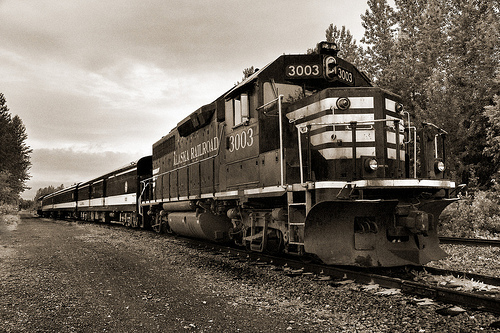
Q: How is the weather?
A: It is cloudy.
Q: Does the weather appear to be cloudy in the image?
A: Yes, it is cloudy.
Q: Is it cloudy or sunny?
A: It is cloudy.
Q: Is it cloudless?
A: No, it is cloudy.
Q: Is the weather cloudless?
A: No, it is cloudy.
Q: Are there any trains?
A: Yes, there is a train.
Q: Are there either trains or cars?
A: Yes, there is a train.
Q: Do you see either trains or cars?
A: Yes, there is a train.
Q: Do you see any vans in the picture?
A: No, there are no vans.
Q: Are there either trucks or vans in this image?
A: No, there are no vans or trucks.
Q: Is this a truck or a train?
A: This is a train.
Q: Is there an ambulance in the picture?
A: No, there are no ambulances.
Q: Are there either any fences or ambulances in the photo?
A: No, there are no ambulances or fences.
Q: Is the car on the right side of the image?
A: No, the car is on the left of the image.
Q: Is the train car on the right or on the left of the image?
A: The car is on the left of the image.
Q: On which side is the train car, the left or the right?
A: The car is on the left of the image.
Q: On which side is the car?
A: The car is on the left of the image.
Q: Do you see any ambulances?
A: No, there are no ambulances.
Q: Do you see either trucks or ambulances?
A: No, there are no ambulances or trucks.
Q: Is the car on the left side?
A: Yes, the car is on the left of the image.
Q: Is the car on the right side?
A: No, the car is on the left of the image.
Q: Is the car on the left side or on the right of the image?
A: The car is on the left of the image.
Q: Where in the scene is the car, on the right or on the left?
A: The car is on the left of the image.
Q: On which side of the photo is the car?
A: The car is on the left of the image.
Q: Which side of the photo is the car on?
A: The car is on the left of the image.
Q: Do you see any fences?
A: No, there are no fences.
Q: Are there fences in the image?
A: No, there are no fences.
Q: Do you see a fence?
A: No, there are no fences.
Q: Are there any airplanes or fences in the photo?
A: No, there are no fences or airplanes.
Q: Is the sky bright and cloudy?
A: Yes, the sky is bright and cloudy.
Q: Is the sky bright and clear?
A: No, the sky is bright but cloudy.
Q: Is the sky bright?
A: Yes, the sky is bright.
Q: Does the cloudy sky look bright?
A: Yes, the sky is bright.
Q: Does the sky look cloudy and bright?
A: Yes, the sky is cloudy and bright.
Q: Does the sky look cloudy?
A: Yes, the sky is cloudy.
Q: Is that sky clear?
A: No, the sky is cloudy.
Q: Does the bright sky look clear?
A: No, the sky is cloudy.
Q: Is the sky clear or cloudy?
A: The sky is cloudy.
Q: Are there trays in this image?
A: No, there are no trays.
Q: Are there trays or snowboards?
A: No, there are no trays or snowboards.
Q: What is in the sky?
A: The clouds are in the sky.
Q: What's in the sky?
A: The clouds are in the sky.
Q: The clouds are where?
A: The clouds are in the sky.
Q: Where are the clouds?
A: The clouds are in the sky.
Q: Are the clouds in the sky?
A: Yes, the clouds are in the sky.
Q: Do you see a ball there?
A: No, there are no balls.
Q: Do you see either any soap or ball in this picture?
A: No, there are no balls or soaps.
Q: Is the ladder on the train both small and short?
A: Yes, the ladder is small and short.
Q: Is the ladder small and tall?
A: No, the ladder is small but short.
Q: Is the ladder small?
A: Yes, the ladder is small.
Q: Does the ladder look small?
A: Yes, the ladder is small.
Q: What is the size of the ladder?
A: The ladder is small.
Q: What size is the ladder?
A: The ladder is small.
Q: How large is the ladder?
A: The ladder is small.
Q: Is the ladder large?
A: No, the ladder is small.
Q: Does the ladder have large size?
A: No, the ladder is small.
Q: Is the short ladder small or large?
A: The ladder is small.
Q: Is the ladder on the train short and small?
A: Yes, the ladder is short and small.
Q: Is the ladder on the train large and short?
A: No, the ladder is short but small.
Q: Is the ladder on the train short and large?
A: No, the ladder is short but small.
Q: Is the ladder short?
A: Yes, the ladder is short.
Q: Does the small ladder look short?
A: Yes, the ladder is short.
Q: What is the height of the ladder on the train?
A: The ladder is short.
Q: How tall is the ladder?
A: The ladder is short.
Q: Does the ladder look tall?
A: No, the ladder is short.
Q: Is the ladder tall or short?
A: The ladder is short.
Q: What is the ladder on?
A: The ladder is on the train.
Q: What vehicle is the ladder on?
A: The ladder is on the train.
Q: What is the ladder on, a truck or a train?
A: The ladder is on a train.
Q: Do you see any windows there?
A: Yes, there is a window.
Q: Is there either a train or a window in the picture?
A: Yes, there is a window.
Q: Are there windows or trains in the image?
A: Yes, there is a window.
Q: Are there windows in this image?
A: Yes, there is a window.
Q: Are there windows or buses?
A: Yes, there is a window.